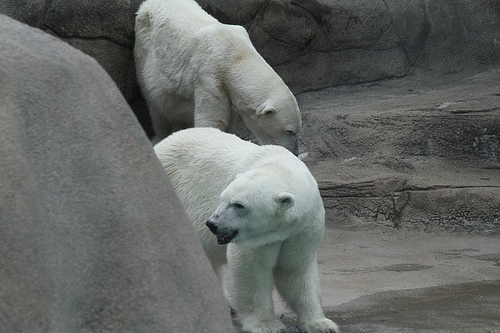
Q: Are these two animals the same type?
A: Yes, all the animals are bears.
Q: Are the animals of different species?
A: No, all the animals are bears.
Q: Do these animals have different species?
A: No, all the animals are bears.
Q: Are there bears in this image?
A: Yes, there is a bear.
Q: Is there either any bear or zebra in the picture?
A: Yes, there is a bear.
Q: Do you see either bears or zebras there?
A: Yes, there is a bear.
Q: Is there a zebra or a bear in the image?
A: Yes, there is a bear.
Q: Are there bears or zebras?
A: Yes, there is a bear.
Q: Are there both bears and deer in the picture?
A: No, there is a bear but no deer.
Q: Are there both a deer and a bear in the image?
A: No, there is a bear but no deer.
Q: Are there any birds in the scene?
A: No, there are no birds.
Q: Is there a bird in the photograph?
A: No, there are no birds.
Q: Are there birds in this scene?
A: No, there are no birds.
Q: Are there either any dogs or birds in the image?
A: No, there are no birds or dogs.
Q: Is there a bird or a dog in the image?
A: No, there are no birds or dogs.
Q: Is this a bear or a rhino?
A: This is a bear.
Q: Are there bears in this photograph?
A: Yes, there is a bear.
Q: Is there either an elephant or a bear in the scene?
A: Yes, there is a bear.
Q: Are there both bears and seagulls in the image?
A: No, there is a bear but no seagulls.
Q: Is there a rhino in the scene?
A: No, there are no rhinos.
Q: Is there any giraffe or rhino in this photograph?
A: No, there are no rhinos or giraffes.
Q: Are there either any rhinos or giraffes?
A: No, there are no rhinos or giraffes.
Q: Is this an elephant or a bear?
A: This is a bear.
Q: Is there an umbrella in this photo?
A: No, there are no umbrellas.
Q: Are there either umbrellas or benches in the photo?
A: No, there are no umbrellas or benches.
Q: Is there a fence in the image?
A: No, there are no fences.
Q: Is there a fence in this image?
A: No, there are no fences.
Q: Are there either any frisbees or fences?
A: No, there are no fences or frisbees.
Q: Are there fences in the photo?
A: No, there are no fences.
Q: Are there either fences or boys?
A: No, there are no fences or boys.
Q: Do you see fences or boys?
A: No, there are no fences or boys.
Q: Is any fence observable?
A: No, there are no fences.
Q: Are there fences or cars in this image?
A: No, there are no fences or cars.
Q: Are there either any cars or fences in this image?
A: No, there are no fences or cars.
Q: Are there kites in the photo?
A: No, there are no kites.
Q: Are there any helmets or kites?
A: No, there are no kites or helmets.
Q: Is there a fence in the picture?
A: No, there are no fences.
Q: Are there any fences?
A: No, there are no fences.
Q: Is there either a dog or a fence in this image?
A: No, there are no fences or dogs.